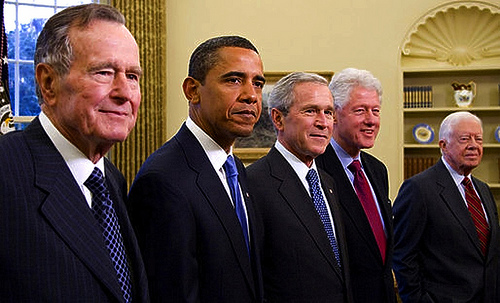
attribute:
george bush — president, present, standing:
[1, 4, 148, 302]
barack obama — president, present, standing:
[128, 35, 266, 302]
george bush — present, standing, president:
[244, 71, 352, 302]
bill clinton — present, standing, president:
[316, 67, 394, 302]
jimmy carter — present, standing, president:
[389, 110, 500, 302]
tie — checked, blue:
[84, 168, 131, 303]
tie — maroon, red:
[348, 161, 386, 267]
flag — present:
[0, 0, 17, 135]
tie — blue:
[222, 157, 250, 259]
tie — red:
[462, 178, 490, 259]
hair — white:
[440, 110, 482, 154]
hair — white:
[328, 66, 382, 109]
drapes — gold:
[93, 1, 166, 195]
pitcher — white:
[450, 80, 476, 109]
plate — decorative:
[410, 124, 434, 143]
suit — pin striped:
[0, 111, 150, 301]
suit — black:
[317, 142, 394, 302]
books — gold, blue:
[404, 84, 433, 108]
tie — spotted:
[306, 169, 341, 267]